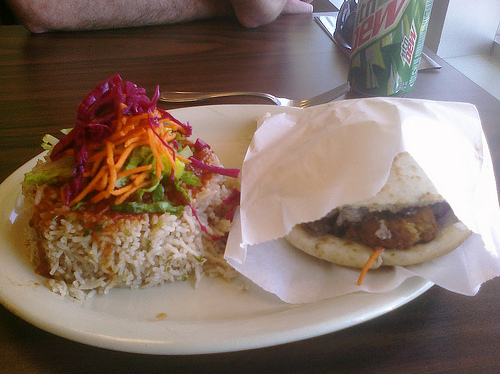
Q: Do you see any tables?
A: Yes, there is a table.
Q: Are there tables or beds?
A: Yes, there is a table.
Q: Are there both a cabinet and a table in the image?
A: No, there is a table but no cabinets.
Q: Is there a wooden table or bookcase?
A: Yes, there is a wood table.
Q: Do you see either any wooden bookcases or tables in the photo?
A: Yes, there is a wood table.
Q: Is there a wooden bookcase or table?
A: Yes, there is a wood table.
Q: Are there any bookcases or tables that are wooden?
A: Yes, the table is wooden.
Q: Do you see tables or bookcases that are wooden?
A: Yes, the table is wooden.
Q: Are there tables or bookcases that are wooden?
A: Yes, the table is wooden.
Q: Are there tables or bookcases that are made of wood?
A: Yes, the table is made of wood.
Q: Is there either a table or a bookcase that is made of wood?
A: Yes, the table is made of wood.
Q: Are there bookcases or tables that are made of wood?
A: Yes, the table is made of wood.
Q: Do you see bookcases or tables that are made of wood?
A: Yes, the table is made of wood.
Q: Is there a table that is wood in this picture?
A: Yes, there is a wood table.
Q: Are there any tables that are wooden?
A: Yes, there is a table that is wooden.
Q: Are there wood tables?
A: Yes, there is a table that is made of wood.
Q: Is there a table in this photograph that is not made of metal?
A: Yes, there is a table that is made of wood.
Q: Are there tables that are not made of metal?
A: Yes, there is a table that is made of wood.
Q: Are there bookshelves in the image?
A: No, there are no bookshelves.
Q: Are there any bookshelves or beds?
A: No, there are no bookshelves or beds.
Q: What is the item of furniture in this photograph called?
A: The piece of furniture is a table.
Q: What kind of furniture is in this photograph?
A: The furniture is a table.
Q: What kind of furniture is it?
A: The piece of furniture is a table.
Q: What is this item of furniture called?
A: This is a table.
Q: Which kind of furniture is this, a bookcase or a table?
A: This is a table.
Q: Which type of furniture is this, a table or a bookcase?
A: This is a table.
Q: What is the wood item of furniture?
A: The piece of furniture is a table.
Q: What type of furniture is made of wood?
A: The furniture is a table.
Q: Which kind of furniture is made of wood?
A: The furniture is a table.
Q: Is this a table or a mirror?
A: This is a table.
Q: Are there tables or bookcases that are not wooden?
A: No, there is a table but it is wooden.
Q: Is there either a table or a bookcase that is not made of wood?
A: No, there is a table but it is made of wood.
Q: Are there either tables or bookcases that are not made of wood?
A: No, there is a table but it is made of wood.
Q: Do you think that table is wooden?
A: Yes, the table is wooden.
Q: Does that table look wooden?
A: Yes, the table is wooden.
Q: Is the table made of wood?
A: Yes, the table is made of wood.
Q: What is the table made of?
A: The table is made of wood.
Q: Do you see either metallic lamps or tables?
A: No, there is a table but it is wooden.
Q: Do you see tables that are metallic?
A: No, there is a table but it is wooden.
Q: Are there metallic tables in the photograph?
A: No, there is a table but it is wooden.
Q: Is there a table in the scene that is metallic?
A: No, there is a table but it is wooden.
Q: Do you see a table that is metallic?
A: No, there is a table but it is wooden.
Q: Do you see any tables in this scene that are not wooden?
A: No, there is a table but it is wooden.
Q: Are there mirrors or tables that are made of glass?
A: No, there is a table but it is made of wood.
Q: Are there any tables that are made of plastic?
A: No, there is a table but it is made of wood.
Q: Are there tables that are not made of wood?
A: No, there is a table but it is made of wood.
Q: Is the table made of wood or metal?
A: The table is made of wood.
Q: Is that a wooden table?
A: Yes, that is a wooden table.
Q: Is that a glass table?
A: No, that is a wooden table.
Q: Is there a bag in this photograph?
A: Yes, there is a bag.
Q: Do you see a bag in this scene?
A: Yes, there is a bag.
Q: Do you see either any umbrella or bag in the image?
A: Yes, there is a bag.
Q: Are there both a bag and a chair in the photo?
A: No, there is a bag but no chairs.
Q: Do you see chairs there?
A: No, there are no chairs.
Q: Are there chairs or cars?
A: No, there are no chairs or cars.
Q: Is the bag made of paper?
A: Yes, the bag is made of paper.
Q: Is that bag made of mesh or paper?
A: The bag is made of paper.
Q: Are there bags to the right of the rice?
A: Yes, there is a bag to the right of the rice.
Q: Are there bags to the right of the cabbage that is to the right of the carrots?
A: Yes, there is a bag to the right of the cabbage.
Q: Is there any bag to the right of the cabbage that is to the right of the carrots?
A: Yes, there is a bag to the right of the cabbage.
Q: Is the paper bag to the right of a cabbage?
A: Yes, the bag is to the right of a cabbage.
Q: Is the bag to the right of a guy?
A: No, the bag is to the right of a cabbage.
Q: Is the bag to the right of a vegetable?
A: Yes, the bag is to the right of a vegetable.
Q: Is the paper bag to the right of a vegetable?
A: Yes, the bag is to the right of a vegetable.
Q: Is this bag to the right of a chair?
A: No, the bag is to the right of a vegetable.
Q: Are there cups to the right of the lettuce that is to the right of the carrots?
A: No, there is a bag to the right of the lettuce.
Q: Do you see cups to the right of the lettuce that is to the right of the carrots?
A: No, there is a bag to the right of the lettuce.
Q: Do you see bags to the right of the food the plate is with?
A: Yes, there is a bag to the right of the food.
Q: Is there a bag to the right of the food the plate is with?
A: Yes, there is a bag to the right of the food.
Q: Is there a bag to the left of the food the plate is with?
A: No, the bag is to the right of the food.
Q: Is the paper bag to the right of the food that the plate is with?
A: Yes, the bag is to the right of the food.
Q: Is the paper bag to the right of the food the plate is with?
A: Yes, the bag is to the right of the food.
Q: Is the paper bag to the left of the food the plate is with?
A: No, the bag is to the right of the food.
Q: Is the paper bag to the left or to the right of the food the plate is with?
A: The bag is to the right of the food.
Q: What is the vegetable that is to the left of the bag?
A: The vegetable is a cabbage.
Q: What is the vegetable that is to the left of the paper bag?
A: The vegetable is a cabbage.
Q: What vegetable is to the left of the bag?
A: The vegetable is a cabbage.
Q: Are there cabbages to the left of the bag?
A: Yes, there is a cabbage to the left of the bag.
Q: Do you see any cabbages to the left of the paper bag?
A: Yes, there is a cabbage to the left of the bag.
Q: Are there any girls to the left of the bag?
A: No, there is a cabbage to the left of the bag.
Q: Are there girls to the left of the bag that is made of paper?
A: No, there is a cabbage to the left of the bag.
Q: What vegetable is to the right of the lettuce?
A: The vegetable is a cabbage.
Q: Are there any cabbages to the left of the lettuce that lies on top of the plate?
A: No, the cabbage is to the right of the lettuce.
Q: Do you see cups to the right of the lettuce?
A: No, there is a cabbage to the right of the lettuce.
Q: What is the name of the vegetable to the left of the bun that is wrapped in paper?
A: The vegetable is a cabbage.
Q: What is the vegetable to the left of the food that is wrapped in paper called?
A: The vegetable is a cabbage.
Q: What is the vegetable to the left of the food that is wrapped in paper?
A: The vegetable is a cabbage.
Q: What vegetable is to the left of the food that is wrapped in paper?
A: The vegetable is a cabbage.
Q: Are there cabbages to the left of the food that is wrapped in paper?
A: Yes, there is a cabbage to the left of the bun.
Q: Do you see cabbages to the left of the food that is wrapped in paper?
A: Yes, there is a cabbage to the left of the bun.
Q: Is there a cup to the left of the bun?
A: No, there is a cabbage to the left of the bun.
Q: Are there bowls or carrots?
A: Yes, there is a carrot.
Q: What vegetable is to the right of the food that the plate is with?
A: The vegetable is a carrot.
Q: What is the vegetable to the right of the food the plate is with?
A: The vegetable is a carrot.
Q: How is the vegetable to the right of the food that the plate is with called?
A: The vegetable is a carrot.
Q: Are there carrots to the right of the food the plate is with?
A: Yes, there is a carrot to the right of the food.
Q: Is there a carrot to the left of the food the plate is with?
A: No, the carrot is to the right of the food.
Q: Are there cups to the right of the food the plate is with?
A: No, there is a carrot to the right of the food.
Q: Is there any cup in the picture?
A: No, there are no cups.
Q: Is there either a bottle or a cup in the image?
A: No, there are no cups or bottles.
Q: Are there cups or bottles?
A: No, there are no cups or bottles.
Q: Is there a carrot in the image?
A: Yes, there are carrots.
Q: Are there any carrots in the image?
A: Yes, there are carrots.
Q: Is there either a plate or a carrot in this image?
A: Yes, there are carrots.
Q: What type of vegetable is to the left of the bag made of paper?
A: The vegetables are carrots.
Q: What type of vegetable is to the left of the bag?
A: The vegetables are carrots.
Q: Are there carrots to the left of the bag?
A: Yes, there are carrots to the left of the bag.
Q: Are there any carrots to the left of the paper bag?
A: Yes, there are carrots to the left of the bag.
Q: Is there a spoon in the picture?
A: No, there are no spoons.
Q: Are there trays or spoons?
A: No, there are no spoons or trays.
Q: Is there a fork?
A: Yes, there is a fork.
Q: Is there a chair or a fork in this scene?
A: Yes, there is a fork.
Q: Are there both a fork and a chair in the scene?
A: No, there is a fork but no chairs.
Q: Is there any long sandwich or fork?
A: Yes, there is a long fork.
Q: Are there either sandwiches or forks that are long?
A: Yes, the fork is long.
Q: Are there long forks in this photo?
A: Yes, there is a long fork.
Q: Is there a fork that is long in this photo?
A: Yes, there is a long fork.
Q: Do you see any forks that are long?
A: Yes, there is a fork that is long.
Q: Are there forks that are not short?
A: Yes, there is a long fork.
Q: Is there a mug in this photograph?
A: No, there are no mugs.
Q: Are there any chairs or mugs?
A: No, there are no mugs or chairs.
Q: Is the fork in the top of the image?
A: Yes, the fork is in the top of the image.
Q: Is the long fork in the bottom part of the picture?
A: No, the fork is in the top of the image.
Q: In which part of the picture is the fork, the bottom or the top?
A: The fork is in the top of the image.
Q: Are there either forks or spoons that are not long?
A: No, there is a fork but it is long.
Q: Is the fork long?
A: Yes, the fork is long.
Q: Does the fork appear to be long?
A: Yes, the fork is long.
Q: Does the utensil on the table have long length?
A: Yes, the fork is long.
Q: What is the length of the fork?
A: The fork is long.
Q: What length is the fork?
A: The fork is long.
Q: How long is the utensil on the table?
A: The fork is long.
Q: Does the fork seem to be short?
A: No, the fork is long.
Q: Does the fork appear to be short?
A: No, the fork is long.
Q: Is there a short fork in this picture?
A: No, there is a fork but it is long.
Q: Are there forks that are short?
A: No, there is a fork but it is long.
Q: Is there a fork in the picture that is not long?
A: No, there is a fork but it is long.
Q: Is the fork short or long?
A: The fork is long.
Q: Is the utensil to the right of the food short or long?
A: The fork is long.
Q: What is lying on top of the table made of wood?
A: The fork is lying on top of the table.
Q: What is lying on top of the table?
A: The fork is lying on top of the table.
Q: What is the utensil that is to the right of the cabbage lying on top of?
A: The fork is lying on top of the table.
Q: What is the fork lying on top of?
A: The fork is lying on top of the table.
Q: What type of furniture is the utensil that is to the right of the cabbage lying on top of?
A: The fork is lying on top of the table.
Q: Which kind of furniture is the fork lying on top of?
A: The fork is lying on top of the table.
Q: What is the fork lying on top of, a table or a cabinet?
A: The fork is lying on top of a table.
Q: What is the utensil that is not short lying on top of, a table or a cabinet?
A: The fork is lying on top of a table.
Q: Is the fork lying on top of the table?
A: Yes, the fork is lying on top of the table.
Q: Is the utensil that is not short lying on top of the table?
A: Yes, the fork is lying on top of the table.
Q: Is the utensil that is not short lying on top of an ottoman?
A: No, the fork is lying on top of the table.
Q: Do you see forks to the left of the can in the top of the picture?
A: Yes, there is a fork to the left of the can.